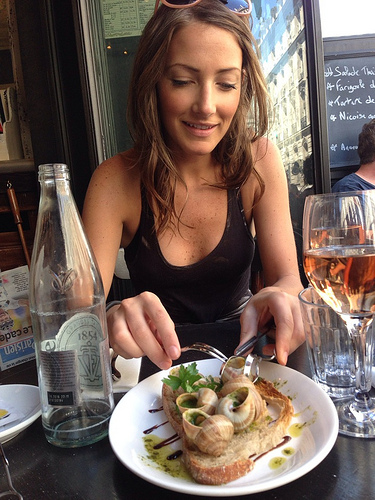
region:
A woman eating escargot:
[59, 0, 355, 497]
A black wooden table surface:
[343, 446, 367, 495]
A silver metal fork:
[179, 339, 232, 364]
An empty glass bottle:
[22, 156, 125, 450]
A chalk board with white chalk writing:
[323, 57, 373, 124]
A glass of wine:
[300, 185, 373, 440]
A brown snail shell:
[175, 407, 235, 460]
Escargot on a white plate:
[103, 354, 352, 497]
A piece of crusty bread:
[181, 454, 256, 486]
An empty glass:
[297, 282, 374, 401]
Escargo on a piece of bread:
[99, 341, 306, 478]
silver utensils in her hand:
[114, 334, 295, 379]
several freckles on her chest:
[178, 197, 225, 260]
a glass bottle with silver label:
[26, 158, 121, 451]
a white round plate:
[100, 335, 351, 495]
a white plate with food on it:
[106, 354, 351, 490]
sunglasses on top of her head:
[146, 0, 263, 26]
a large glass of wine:
[303, 178, 374, 442]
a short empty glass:
[301, 293, 374, 404]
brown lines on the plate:
[143, 395, 191, 483]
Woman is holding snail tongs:
[219, 315, 297, 388]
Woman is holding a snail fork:
[103, 341, 227, 381]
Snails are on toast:
[182, 356, 264, 453]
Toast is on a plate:
[162, 371, 292, 481]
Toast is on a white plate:
[158, 361, 291, 482]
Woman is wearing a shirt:
[113, 136, 270, 323]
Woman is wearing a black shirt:
[120, 141, 267, 324]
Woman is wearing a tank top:
[120, 139, 268, 324]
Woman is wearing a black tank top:
[120, 138, 263, 325]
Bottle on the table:
[15, 163, 117, 449]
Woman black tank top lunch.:
[119, 1, 285, 495]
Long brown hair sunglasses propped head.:
[133, 0, 266, 168]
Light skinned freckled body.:
[93, 83, 288, 271]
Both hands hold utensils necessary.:
[110, 291, 309, 364]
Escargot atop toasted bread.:
[158, 360, 312, 473]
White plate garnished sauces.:
[112, 359, 342, 489]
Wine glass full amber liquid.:
[295, 173, 374, 414]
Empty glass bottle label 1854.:
[26, 156, 110, 452]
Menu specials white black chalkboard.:
[316, 37, 373, 181]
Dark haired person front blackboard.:
[331, 113, 374, 184]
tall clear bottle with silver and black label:
[23, 159, 117, 453]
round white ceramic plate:
[106, 352, 341, 499]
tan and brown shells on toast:
[160, 367, 294, 478]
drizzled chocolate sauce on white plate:
[134, 404, 180, 465]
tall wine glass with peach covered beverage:
[297, 189, 371, 446]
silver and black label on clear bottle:
[35, 344, 84, 413]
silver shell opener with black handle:
[218, 321, 280, 390]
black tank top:
[122, 147, 259, 328]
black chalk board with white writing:
[322, 49, 371, 174]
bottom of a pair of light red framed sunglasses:
[159, 0, 257, 17]